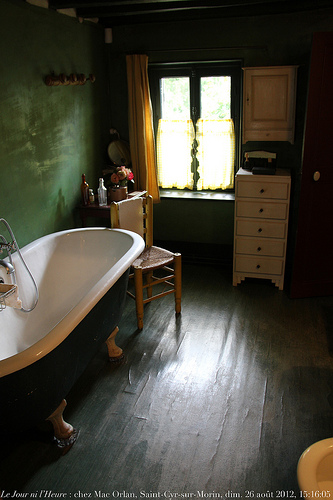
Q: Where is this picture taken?
A: A bathroom.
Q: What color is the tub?
A: White.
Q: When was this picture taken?
A: Daytime.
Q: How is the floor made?
A: Of wood.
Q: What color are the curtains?
A: Yellow.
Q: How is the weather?
A: Sunny.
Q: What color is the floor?
A: Black.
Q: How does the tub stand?
A: On feet.